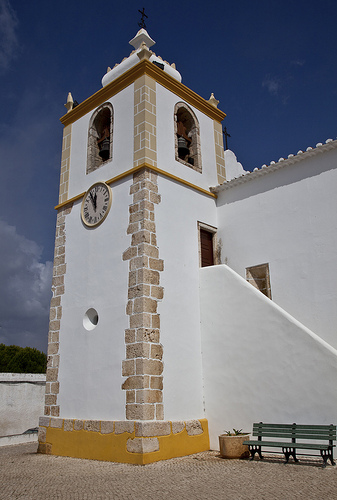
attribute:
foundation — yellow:
[40, 419, 214, 466]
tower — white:
[46, 8, 233, 424]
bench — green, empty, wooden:
[246, 423, 336, 468]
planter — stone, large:
[217, 428, 251, 459]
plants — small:
[226, 429, 247, 437]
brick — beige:
[132, 79, 157, 413]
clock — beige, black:
[77, 181, 116, 229]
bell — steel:
[96, 131, 113, 156]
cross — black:
[134, 4, 152, 32]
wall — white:
[220, 165, 335, 319]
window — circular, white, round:
[80, 307, 100, 332]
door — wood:
[200, 226, 217, 269]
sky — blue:
[2, 2, 336, 128]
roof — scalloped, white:
[211, 136, 335, 206]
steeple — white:
[96, 28, 186, 77]